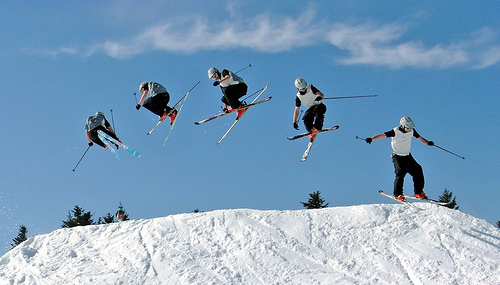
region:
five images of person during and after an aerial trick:
[62, 50, 467, 206]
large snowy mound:
[2, 200, 492, 280]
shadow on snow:
[451, 220, 496, 260]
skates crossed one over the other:
[285, 116, 340, 157]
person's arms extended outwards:
[360, 127, 437, 147]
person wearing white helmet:
[398, 110, 415, 131]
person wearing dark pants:
[390, 150, 425, 187]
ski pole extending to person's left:
[61, 135, 87, 175]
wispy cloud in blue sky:
[35, 2, 496, 78]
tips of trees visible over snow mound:
[13, 203, 130, 247]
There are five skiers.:
[55, 52, 473, 219]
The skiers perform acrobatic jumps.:
[56, 55, 468, 217]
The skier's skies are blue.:
[92, 125, 144, 166]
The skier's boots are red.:
[219, 100, 259, 126]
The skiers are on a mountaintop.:
[3, 185, 496, 283]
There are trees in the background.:
[7, 200, 143, 254]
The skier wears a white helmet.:
[285, 71, 313, 96]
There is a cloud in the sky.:
[23, 1, 495, 58]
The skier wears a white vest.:
[382, 122, 424, 167]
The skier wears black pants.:
[387, 149, 427, 194]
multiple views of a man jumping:
[68, 58, 458, 211]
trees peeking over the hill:
[11, 207, 144, 239]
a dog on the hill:
[111, 205, 129, 220]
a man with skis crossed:
[278, 75, 344, 153]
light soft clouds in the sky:
[34, 17, 467, 78]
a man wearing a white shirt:
[370, 108, 447, 208]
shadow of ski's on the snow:
[451, 217, 496, 254]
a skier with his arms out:
[357, 90, 463, 220]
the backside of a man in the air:
[75, 109, 147, 170]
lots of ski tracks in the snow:
[75, 218, 398, 276]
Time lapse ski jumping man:
[72, 58, 450, 205]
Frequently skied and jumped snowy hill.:
[15, 195, 497, 283]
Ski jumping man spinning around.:
[71, 111, 140, 163]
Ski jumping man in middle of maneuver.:
[196, 64, 277, 153]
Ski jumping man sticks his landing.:
[366, 114, 460, 214]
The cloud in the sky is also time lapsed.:
[31, 6, 499, 81]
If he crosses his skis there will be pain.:
[132, 63, 349, 165]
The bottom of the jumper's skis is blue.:
[64, 98, 144, 177]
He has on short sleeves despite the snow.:
[367, 118, 432, 173]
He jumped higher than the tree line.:
[13, 196, 493, 237]